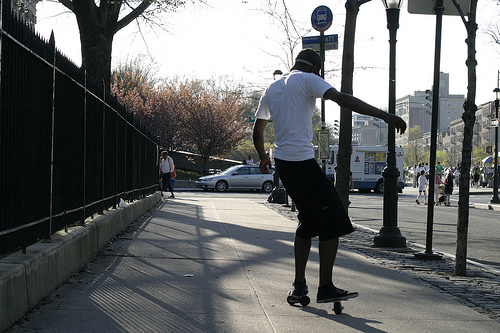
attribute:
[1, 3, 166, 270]
fence — black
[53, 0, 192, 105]
tree — large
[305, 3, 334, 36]
sign — blue, white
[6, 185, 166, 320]
base — cement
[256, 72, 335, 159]
shirt — white, short-sleeve